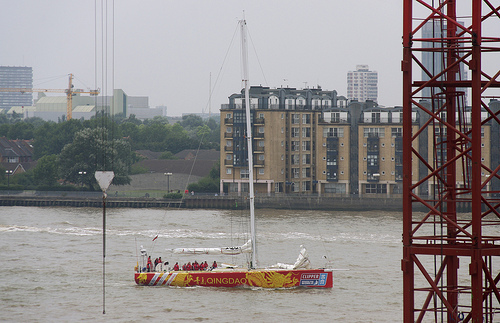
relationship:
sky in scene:
[2, 3, 500, 114] [1, 1, 500, 322]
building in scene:
[216, 80, 500, 198] [1, 1, 500, 322]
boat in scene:
[133, 14, 336, 291] [1, 1, 500, 322]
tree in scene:
[56, 124, 132, 195] [1, 1, 500, 322]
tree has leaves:
[56, 124, 132, 195] [58, 123, 133, 185]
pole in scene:
[236, 21, 260, 265] [1, 1, 500, 322]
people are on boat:
[142, 253, 224, 271] [133, 14, 336, 291]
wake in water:
[1, 223, 313, 243] [2, 202, 500, 322]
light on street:
[163, 171, 175, 191] [2, 184, 499, 207]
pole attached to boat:
[236, 21, 260, 265] [133, 14, 336, 291]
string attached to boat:
[161, 24, 241, 251] [133, 14, 336, 291]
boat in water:
[133, 14, 336, 291] [2, 202, 500, 322]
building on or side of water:
[216, 80, 500, 198] [2, 202, 500, 322]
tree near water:
[56, 124, 132, 195] [2, 202, 500, 322]